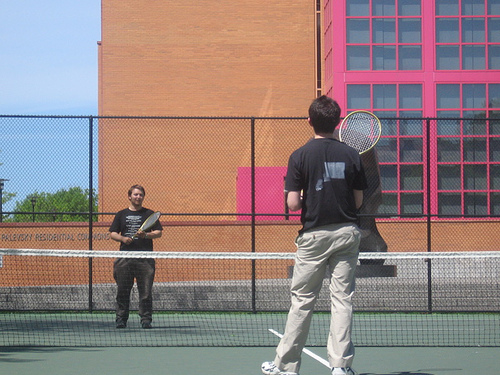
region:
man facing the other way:
[258, 80, 385, 373]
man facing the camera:
[98, 169, 184, 336]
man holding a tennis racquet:
[102, 172, 181, 334]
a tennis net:
[172, 238, 277, 363]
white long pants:
[253, 201, 417, 374]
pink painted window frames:
[394, 2, 494, 222]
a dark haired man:
[287, 81, 353, 144]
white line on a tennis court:
[229, 296, 359, 373]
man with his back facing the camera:
[260, 73, 405, 342]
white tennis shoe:
[257, 341, 313, 373]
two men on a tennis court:
[98, 89, 460, 369]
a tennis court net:
[1, 242, 225, 362]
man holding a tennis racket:
[96, 182, 193, 250]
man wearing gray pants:
[277, 220, 359, 372]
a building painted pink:
[325, 4, 499, 99]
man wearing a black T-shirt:
[278, 140, 369, 222]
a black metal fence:
[3, 110, 101, 242]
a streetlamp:
[22, 187, 48, 221]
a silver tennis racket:
[339, 105, 395, 158]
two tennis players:
[76, 86, 381, 369]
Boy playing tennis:
[287, 72, 373, 374]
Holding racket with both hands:
[112, 175, 169, 337]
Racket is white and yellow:
[340, 105, 390, 150]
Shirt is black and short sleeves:
[282, 117, 367, 224]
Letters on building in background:
[2, 229, 112, 243]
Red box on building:
[228, 154, 311, 224]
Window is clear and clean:
[395, 84, 422, 109]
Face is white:
[126, 185, 146, 207]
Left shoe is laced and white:
[261, 355, 282, 373]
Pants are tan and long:
[285, 227, 364, 363]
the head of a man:
[123, 181, 150, 208]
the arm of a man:
[106, 210, 121, 240]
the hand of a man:
[121, 230, 136, 246]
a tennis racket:
[121, 208, 168, 250]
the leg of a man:
[261, 244, 331, 369]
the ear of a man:
[304, 112, 316, 129]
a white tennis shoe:
[253, 354, 303, 374]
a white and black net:
[1, 243, 498, 348]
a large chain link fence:
[0, 110, 498, 316]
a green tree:
[12, 178, 108, 225]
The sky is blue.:
[13, 12, 81, 112]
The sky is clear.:
[7, 5, 84, 100]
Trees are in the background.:
[13, 169, 88, 212]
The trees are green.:
[21, 182, 86, 216]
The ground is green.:
[113, 348, 217, 370]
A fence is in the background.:
[0, 98, 272, 321]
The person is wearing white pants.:
[239, 220, 383, 373]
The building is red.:
[118, 13, 270, 105]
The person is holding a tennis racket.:
[291, 103, 395, 225]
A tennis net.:
[1, 245, 498, 361]